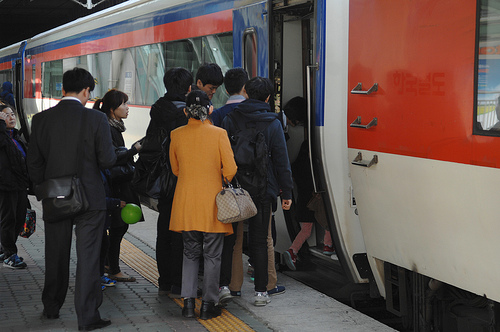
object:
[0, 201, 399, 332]
platform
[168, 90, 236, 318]
woman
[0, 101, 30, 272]
woman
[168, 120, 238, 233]
coat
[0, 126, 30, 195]
coat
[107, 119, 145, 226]
coat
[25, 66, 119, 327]
man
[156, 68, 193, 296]
man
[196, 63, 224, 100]
man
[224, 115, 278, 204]
backpack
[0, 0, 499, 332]
train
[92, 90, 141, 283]
child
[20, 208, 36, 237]
purse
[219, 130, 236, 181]
arm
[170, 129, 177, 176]
arm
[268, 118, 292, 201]
arm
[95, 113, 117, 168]
arm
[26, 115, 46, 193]
arm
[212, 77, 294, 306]
man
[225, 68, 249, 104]
man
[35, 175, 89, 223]
bag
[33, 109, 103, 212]
back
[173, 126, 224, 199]
back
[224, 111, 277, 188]
back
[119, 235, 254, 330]
stripe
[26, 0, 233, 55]
stripe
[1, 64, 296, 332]
group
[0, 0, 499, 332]
station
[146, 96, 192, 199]
jacket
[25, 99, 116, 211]
jacket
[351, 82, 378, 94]
handle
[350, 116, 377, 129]
handle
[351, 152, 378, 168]
handle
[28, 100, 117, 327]
suit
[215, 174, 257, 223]
handbag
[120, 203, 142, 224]
ball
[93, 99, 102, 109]
ponytail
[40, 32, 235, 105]
window